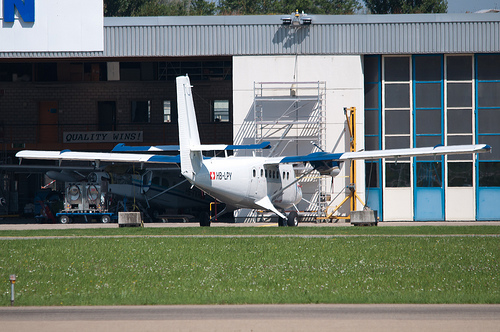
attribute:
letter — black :
[206, 162, 242, 184]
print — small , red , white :
[208, 172, 217, 181]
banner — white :
[54, 128, 155, 145]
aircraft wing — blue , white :
[275, 137, 495, 167]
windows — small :
[360, 54, 495, 185]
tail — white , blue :
[106, 71, 277, 168]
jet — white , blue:
[0, 69, 497, 227]